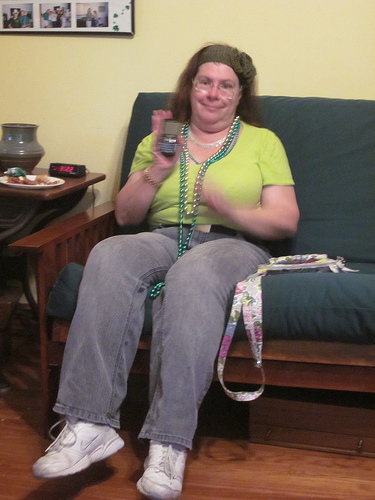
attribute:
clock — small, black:
[47, 161, 86, 179]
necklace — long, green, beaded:
[145, 117, 250, 300]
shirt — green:
[126, 121, 295, 223]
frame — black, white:
[4, 27, 133, 39]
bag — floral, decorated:
[221, 257, 342, 360]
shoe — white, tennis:
[31, 416, 123, 479]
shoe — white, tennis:
[135, 439, 186, 498]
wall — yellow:
[2, 2, 372, 231]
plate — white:
[0, 167, 65, 187]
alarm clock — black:
[46, 161, 88, 179]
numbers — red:
[55, 164, 72, 172]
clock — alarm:
[45, 162, 88, 178]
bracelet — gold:
[140, 170, 160, 189]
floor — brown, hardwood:
[0, 306, 358, 497]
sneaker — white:
[30, 409, 126, 483]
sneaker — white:
[133, 433, 186, 497]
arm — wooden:
[6, 194, 126, 255]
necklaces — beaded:
[150, 113, 243, 304]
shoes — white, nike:
[29, 407, 125, 484]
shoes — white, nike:
[133, 430, 188, 498]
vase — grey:
[2, 122, 46, 171]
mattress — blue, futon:
[46, 85, 363, 344]